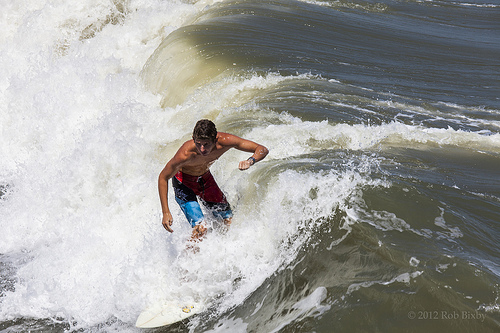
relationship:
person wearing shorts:
[157, 119, 270, 249] [172, 167, 232, 225]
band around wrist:
[244, 155, 257, 164] [246, 153, 260, 165]